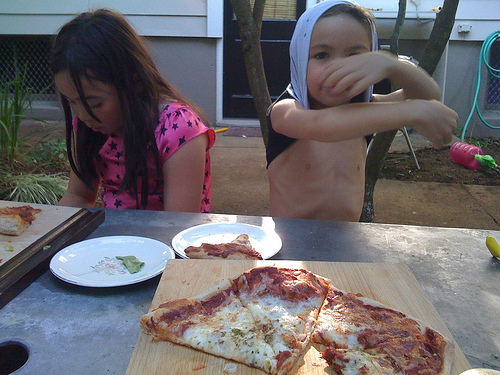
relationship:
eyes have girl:
[64, 97, 128, 101] [24, 24, 191, 198]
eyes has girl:
[64, 97, 128, 101] [24, 24, 191, 198]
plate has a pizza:
[176, 221, 274, 261] [187, 235, 256, 256]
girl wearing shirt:
[40, 15, 242, 235] [68, 92, 219, 215]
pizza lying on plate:
[181, 232, 264, 261] [170, 220, 284, 259]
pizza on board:
[137, 263, 458, 373] [123, 258, 475, 374]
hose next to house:
[457, 32, 500, 143] [1, 1, 497, 145]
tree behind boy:
[235, 3, 466, 220] [258, 0, 465, 224]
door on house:
[219, 0, 315, 124] [1, 1, 497, 145]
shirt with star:
[68, 99, 218, 215] [170, 122, 179, 131]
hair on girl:
[47, 8, 165, 210] [45, 9, 212, 216]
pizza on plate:
[181, 218, 276, 281] [166, 186, 301, 296]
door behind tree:
[219, 0, 315, 124] [219, 0, 461, 218]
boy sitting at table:
[258, 0, 465, 224] [3, 208, 499, 373]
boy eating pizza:
[258, 0, 465, 224] [137, 263, 458, 373]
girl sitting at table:
[48, 5, 219, 215] [3, 208, 499, 373]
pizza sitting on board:
[137, 263, 458, 373] [123, 258, 475, 374]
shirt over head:
[68, 92, 219, 215] [47, 19, 148, 136]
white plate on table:
[47, 234, 176, 291] [3, 208, 499, 373]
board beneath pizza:
[123, 258, 473, 374] [137, 263, 458, 373]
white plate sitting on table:
[43, 232, 175, 291] [58, 204, 490, 373]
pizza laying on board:
[0, 202, 44, 239] [143, 257, 451, 373]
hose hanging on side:
[452, 32, 498, 137] [0, 12, 494, 142]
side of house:
[0, 12, 494, 142] [1, 1, 497, 145]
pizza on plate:
[181, 232, 264, 261] [170, 220, 284, 259]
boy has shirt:
[258, 0, 462, 232] [280, 5, 326, 112]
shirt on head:
[280, 5, 326, 112] [295, 3, 377, 104]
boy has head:
[258, 0, 462, 232] [295, 3, 377, 104]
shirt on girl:
[68, 92, 219, 215] [38, 10, 221, 209]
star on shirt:
[109, 195, 123, 209] [68, 112, 215, 226]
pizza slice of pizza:
[137, 263, 333, 374] [162, 261, 445, 371]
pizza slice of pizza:
[142, 283, 273, 368] [162, 261, 445, 371]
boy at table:
[258, 0, 465, 224] [12, 195, 489, 372]